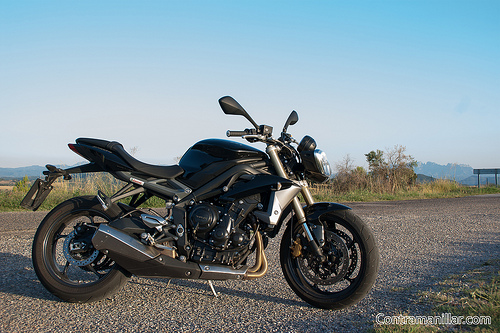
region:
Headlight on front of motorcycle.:
[296, 145, 342, 190]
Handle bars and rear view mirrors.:
[190, 91, 320, 168]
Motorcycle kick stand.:
[162, 268, 243, 315]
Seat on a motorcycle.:
[100, 125, 180, 195]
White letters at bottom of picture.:
[355, 304, 495, 328]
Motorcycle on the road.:
[46, 86, 371, 313]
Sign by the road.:
[451, 150, 496, 232]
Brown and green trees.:
[340, 119, 431, 196]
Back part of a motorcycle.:
[0, 156, 78, 216]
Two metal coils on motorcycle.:
[235, 230, 287, 319]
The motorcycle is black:
[23, 97, 382, 304]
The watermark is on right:
[375, 305, 492, 331]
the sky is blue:
[0, 0, 497, 170]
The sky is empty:
[0, 0, 498, 170]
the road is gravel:
[0, 194, 499, 329]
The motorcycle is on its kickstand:
[17, 92, 382, 307]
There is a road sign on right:
[470, 163, 499, 193]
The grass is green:
[1, 163, 498, 208]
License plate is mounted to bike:
[15, 177, 53, 209]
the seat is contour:
[70, 127, 193, 186]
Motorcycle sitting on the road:
[52, 52, 377, 280]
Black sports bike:
[51, 67, 359, 281]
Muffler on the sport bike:
[58, 202, 272, 298]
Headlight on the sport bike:
[213, 83, 388, 226]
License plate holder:
[15, 125, 58, 230]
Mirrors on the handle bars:
[213, 90, 293, 158]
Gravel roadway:
[326, 196, 466, 319]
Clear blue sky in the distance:
[281, 50, 466, 186]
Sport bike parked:
[20, 90, 348, 325]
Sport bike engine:
[183, 192, 273, 284]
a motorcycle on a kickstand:
[27, 83, 384, 315]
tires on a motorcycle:
[25, 197, 393, 309]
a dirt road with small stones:
[380, 197, 490, 262]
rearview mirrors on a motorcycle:
[210, 87, 313, 127]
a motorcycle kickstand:
[200, 277, 227, 299]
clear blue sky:
[10, 5, 486, 75]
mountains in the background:
[0, 155, 85, 176]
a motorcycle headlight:
[297, 146, 338, 186]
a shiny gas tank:
[177, 135, 268, 176]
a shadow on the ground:
[0, 232, 104, 314]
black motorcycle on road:
[30, 88, 433, 329]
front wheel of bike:
[258, 200, 371, 319]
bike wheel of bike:
[40, 195, 161, 302]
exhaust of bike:
[17, 175, 56, 214]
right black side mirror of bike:
[212, 91, 253, 123]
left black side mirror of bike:
[275, 108, 302, 125]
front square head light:
[297, 138, 332, 187]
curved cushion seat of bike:
[80, 120, 197, 189]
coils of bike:
[245, 234, 274, 283]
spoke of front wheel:
[305, 230, 359, 279]